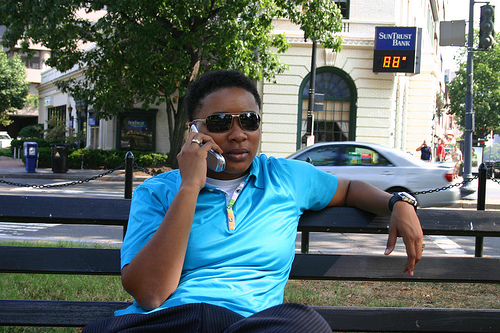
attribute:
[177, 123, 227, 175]
phone — silver, flip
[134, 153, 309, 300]
shirt — blue, polo, shiny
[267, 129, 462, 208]
car — silver, four-door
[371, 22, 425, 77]
temperature sign — showing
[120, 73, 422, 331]
man — African-American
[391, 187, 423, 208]
wristwatch — black, silver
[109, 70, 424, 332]
woman — walking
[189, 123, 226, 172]
phone — silvery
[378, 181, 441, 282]
wrist — man's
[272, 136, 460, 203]
grey car — driving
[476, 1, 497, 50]
traffic light — rear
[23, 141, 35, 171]
magazine stand — blue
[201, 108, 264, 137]
sunglasses — silver framed, aviator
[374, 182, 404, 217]
wristband — black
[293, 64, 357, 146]
window — large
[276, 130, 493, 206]
sedan — silver, moving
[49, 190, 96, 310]
bench — dark, wood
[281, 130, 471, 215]
sedan — silver, four door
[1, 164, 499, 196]
chain — black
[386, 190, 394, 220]
band — black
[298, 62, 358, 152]
frame — green